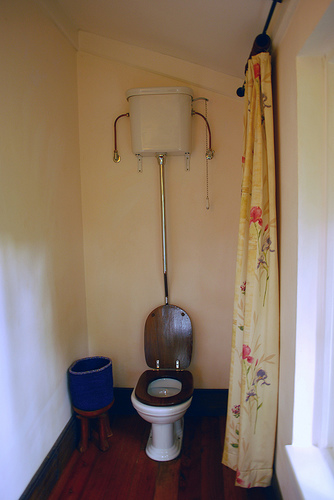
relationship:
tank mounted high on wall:
[125, 86, 196, 157] [84, 29, 246, 407]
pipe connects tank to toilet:
[159, 154, 169, 302] [132, 308, 192, 462]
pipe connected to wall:
[111, 102, 129, 162] [84, 29, 246, 407]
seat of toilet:
[134, 305, 194, 406] [132, 308, 192, 462]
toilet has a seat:
[132, 308, 192, 462] [134, 305, 194, 406]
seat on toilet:
[134, 305, 194, 406] [132, 308, 192, 462]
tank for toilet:
[125, 86, 196, 157] [132, 308, 192, 462]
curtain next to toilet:
[221, 52, 282, 494] [132, 308, 192, 462]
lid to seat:
[143, 301, 193, 373] [134, 305, 194, 406]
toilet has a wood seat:
[132, 308, 192, 462] [134, 305, 194, 406]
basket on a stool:
[70, 356, 113, 408] [72, 397, 121, 455]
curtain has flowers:
[221, 52, 282, 494] [239, 201, 273, 394]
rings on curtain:
[248, 31, 271, 65] [221, 52, 282, 494]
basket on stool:
[70, 356, 113, 408] [72, 397, 121, 455]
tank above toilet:
[125, 86, 196, 157] [132, 308, 192, 462]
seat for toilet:
[134, 305, 194, 406] [132, 308, 192, 462]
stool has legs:
[72, 397, 121, 455] [77, 416, 117, 450]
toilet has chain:
[107, 73, 221, 466] [190, 93, 217, 212]